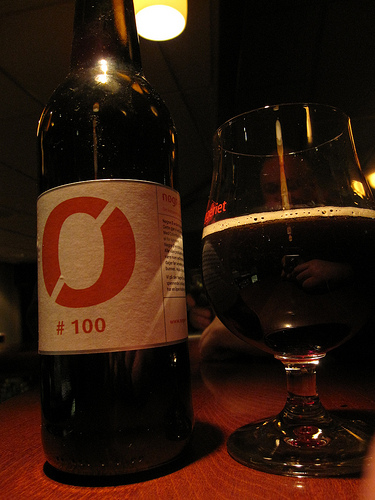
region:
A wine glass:
[222, 161, 347, 192]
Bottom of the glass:
[227, 297, 353, 326]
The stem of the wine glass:
[290, 370, 311, 402]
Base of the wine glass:
[271, 452, 341, 468]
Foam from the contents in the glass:
[253, 213, 269, 219]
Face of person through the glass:
[265, 168, 278, 197]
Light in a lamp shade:
[145, 11, 169, 35]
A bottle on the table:
[50, 370, 167, 455]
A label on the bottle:
[148, 200, 179, 277]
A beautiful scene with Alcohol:
[3, 5, 371, 496]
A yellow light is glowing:
[113, 2, 207, 70]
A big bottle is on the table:
[10, 4, 198, 472]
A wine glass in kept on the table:
[200, 90, 367, 482]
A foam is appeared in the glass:
[196, 97, 370, 477]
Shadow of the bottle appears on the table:
[22, 334, 223, 492]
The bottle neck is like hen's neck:
[11, 6, 201, 476]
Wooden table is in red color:
[7, 186, 374, 497]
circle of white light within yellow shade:
[129, 0, 186, 39]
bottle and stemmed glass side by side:
[36, 0, 368, 486]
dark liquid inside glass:
[201, 126, 367, 477]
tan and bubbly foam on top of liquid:
[201, 201, 369, 246]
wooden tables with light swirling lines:
[2, 338, 368, 490]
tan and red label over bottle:
[33, 172, 186, 353]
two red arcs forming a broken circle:
[39, 195, 134, 305]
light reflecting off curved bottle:
[32, 53, 175, 188]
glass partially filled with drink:
[199, 99, 368, 387]